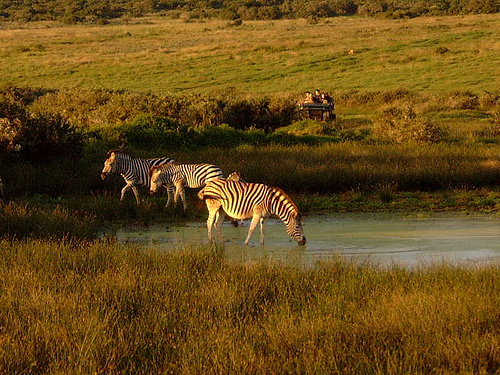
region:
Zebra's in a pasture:
[93, 125, 335, 243]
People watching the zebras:
[293, 79, 352, 121]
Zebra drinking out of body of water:
[188, 195, 329, 262]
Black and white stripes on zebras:
[98, 48, 301, 263]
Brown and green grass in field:
[89, 4, 461, 81]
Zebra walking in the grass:
[96, 137, 161, 208]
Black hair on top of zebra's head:
[100, 146, 145, 166]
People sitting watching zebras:
[293, 85, 360, 156]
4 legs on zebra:
[194, 210, 276, 252]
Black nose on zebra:
[292, 238, 314, 250]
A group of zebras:
[83, 132, 329, 262]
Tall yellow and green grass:
[34, 250, 456, 366]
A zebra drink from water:
[188, 175, 359, 275]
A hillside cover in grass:
[21, 20, 487, 129]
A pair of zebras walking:
[101, 141, 225, 219]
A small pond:
[316, 196, 494, 280]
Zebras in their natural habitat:
[81, 135, 342, 265]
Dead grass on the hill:
[19, 14, 398, 89]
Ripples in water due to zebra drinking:
[265, 215, 428, 264]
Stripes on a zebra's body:
[212, 177, 282, 234]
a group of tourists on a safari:
[293, 90, 333, 123]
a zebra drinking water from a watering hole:
[198, 178, 305, 248]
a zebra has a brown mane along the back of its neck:
[274, 184, 299, 219]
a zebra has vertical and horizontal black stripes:
[149, 163, 222, 210]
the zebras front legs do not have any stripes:
[242, 213, 258, 245]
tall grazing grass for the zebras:
[0, 238, 499, 373]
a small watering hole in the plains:
[97, 188, 497, 272]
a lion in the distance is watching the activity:
[344, 46, 355, 56]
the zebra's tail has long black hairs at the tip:
[197, 188, 224, 200]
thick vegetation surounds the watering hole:
[0, 87, 296, 152]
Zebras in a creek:
[86, 141, 314, 265]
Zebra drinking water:
[194, 174, 315, 256]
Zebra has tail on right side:
[186, 174, 314, 255]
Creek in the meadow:
[100, 206, 496, 266]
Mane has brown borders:
[271, 186, 305, 218]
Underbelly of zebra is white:
[219, 214, 256, 221]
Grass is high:
[14, 256, 496, 365]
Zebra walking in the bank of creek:
[94, 146, 179, 210]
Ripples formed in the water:
[302, 233, 445, 261]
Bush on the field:
[357, 100, 458, 147]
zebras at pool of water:
[82, 71, 337, 277]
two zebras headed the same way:
[90, 135, 200, 220]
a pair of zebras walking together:
[91, 140, 187, 210]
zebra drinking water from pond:
[176, 165, 316, 260]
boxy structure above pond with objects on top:
[281, 65, 346, 130]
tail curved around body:
[175, 165, 220, 210]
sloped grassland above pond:
[72, 15, 457, 226]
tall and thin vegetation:
[71, 238, 436, 353]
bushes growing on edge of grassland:
[11, 65, 231, 135]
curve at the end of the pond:
[56, 141, 346, 316]